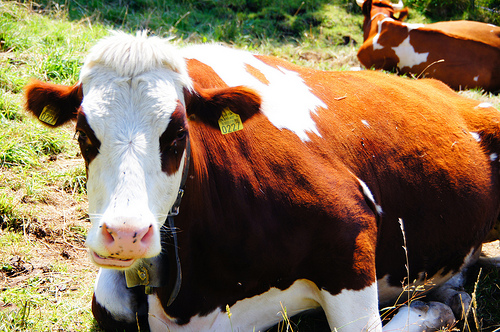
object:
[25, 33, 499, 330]
cow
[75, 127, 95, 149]
eye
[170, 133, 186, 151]
eye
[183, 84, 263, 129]
ear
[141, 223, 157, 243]
nostril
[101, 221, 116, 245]
nostril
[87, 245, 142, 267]
mouth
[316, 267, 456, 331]
leg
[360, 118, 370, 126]
spot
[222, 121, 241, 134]
number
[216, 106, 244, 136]
tag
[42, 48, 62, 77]
grass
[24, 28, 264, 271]
head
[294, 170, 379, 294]
shoulder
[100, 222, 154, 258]
nose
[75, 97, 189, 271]
face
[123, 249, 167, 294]
bell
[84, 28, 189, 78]
fur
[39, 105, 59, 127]
tag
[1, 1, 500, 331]
hill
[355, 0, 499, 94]
cow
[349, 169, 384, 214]
spot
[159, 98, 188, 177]
fur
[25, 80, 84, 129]
ear